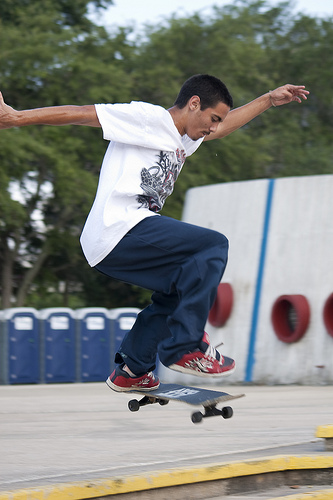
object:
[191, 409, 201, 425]
wheels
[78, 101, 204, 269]
shirt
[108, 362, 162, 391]
shoe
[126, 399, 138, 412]
wheel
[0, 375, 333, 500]
ground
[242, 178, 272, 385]
pole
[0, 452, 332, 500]
line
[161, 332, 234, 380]
shoes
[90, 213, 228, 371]
pants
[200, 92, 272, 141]
arm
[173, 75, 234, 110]
hair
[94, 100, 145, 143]
sleeve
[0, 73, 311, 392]
man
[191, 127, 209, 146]
mustache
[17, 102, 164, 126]
arms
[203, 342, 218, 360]
laces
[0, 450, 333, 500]
stripe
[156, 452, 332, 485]
curb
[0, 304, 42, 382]
buildings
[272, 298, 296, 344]
openings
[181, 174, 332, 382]
concrete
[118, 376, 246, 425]
skateboard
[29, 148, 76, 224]
leaves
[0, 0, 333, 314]
tree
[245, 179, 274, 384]
stripe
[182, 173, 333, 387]
wall